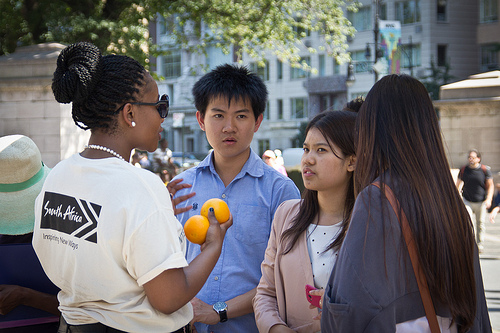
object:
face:
[132, 72, 165, 154]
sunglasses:
[131, 93, 170, 118]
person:
[455, 148, 493, 252]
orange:
[209, 206, 226, 219]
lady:
[30, 42, 233, 332]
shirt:
[251, 199, 350, 333]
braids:
[50, 42, 99, 105]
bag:
[368, 180, 457, 333]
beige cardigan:
[252, 212, 322, 333]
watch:
[213, 301, 228, 322]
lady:
[251, 110, 356, 333]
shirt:
[306, 220, 344, 289]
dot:
[324, 233, 327, 235]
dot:
[312, 239, 315, 242]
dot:
[317, 252, 319, 255]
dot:
[323, 263, 325, 266]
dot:
[336, 254, 338, 255]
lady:
[320, 73, 491, 333]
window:
[162, 55, 181, 78]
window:
[290, 56, 310, 79]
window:
[158, 13, 174, 35]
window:
[277, 59, 283, 79]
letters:
[43, 201, 82, 223]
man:
[169, 66, 302, 333]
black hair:
[343, 74, 477, 330]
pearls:
[84, 144, 129, 164]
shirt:
[169, 150, 302, 333]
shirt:
[31, 153, 194, 332]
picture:
[40, 192, 103, 244]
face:
[204, 94, 255, 156]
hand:
[200, 207, 233, 251]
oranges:
[184, 198, 231, 244]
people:
[32, 40, 493, 333]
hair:
[343, 76, 492, 325]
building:
[153, 0, 478, 173]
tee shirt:
[31, 153, 195, 333]